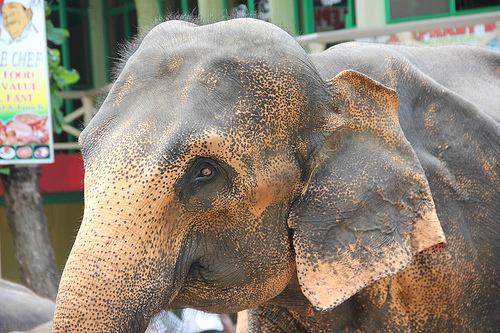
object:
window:
[383, 0, 456, 23]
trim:
[44, 1, 499, 41]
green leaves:
[43, 4, 80, 141]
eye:
[185, 158, 219, 186]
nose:
[48, 212, 194, 333]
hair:
[90, 10, 272, 110]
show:
[362, 48, 498, 240]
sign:
[0, 4, 57, 166]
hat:
[3, 1, 34, 8]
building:
[5, 3, 499, 291]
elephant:
[55, 16, 499, 332]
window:
[91, 16, 146, 85]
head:
[78, 18, 305, 313]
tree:
[2, 159, 64, 304]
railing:
[22, 57, 109, 180]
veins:
[302, 183, 428, 256]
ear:
[287, 67, 448, 313]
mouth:
[167, 241, 232, 311]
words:
[2, 38, 42, 106]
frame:
[301, 2, 317, 34]